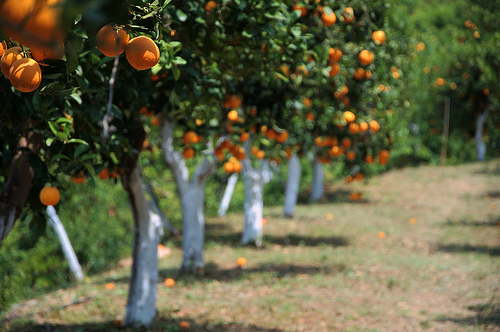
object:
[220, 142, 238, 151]
oranges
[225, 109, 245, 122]
oranges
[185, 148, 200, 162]
oranges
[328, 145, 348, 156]
oranges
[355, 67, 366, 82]
oranges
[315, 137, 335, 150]
oranges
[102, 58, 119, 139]
branches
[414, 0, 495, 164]
trees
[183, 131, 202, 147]
orange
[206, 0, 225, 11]
orange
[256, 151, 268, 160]
orange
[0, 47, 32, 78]
orange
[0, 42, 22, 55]
orange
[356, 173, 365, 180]
orange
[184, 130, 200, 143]
fruits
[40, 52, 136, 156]
tree leaves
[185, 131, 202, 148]
oranges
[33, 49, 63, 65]
oranges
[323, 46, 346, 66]
oranges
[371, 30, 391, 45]
oranges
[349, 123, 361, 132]
oranges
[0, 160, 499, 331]
ground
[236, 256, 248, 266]
fruit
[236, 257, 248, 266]
fruit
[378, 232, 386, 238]
fruit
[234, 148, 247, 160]
fruit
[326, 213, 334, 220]
fruit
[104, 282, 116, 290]
fruit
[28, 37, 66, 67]
hangingfruits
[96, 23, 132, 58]
hangingfruits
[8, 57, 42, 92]
hangingfruits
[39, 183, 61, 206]
hangingfruits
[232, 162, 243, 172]
hangingfruits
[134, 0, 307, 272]
tree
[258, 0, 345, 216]
tree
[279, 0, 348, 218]
tree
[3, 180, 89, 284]
trees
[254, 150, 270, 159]
oranges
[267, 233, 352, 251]
shadow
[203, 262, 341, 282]
shadow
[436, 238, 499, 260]
shadow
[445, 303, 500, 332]
shadow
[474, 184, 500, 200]
shadow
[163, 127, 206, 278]
line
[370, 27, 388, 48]
fruit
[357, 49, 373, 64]
fruit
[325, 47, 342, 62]
fruit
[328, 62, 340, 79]
fruit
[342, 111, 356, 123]
fruit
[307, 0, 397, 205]
tree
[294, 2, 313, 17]
orange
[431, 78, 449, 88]
oranges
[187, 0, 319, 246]
trees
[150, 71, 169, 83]
orange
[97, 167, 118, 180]
orange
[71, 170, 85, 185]
orange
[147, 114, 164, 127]
orange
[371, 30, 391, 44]
orange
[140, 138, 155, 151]
orange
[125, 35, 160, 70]
fruits